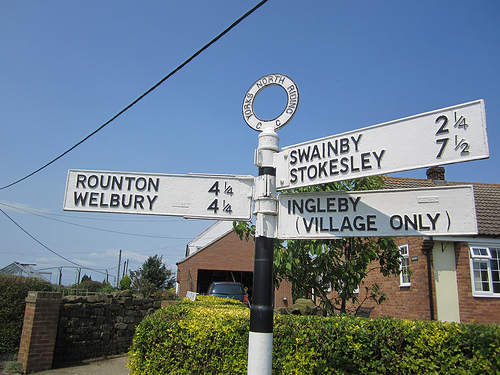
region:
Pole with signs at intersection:
[62, 70, 489, 372]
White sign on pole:
[275, 99, 489, 189]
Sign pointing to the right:
[281, 185, 481, 240]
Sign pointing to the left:
[61, 165, 253, 222]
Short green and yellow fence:
[126, 300, 496, 373]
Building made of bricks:
[176, 175, 498, 321]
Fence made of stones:
[59, 289, 150, 362]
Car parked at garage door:
[207, 279, 245, 306]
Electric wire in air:
[0, 20, 232, 195]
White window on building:
[473, 242, 499, 294]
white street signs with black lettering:
[60, 96, 496, 254]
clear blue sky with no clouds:
[327, 25, 484, 60]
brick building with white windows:
[180, 166, 498, 317]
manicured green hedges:
[139, 312, 476, 371]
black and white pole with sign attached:
[234, 58, 319, 373]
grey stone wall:
[54, 276, 156, 352]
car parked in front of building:
[192, 263, 252, 312]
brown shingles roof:
[475, 175, 495, 240]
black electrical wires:
[2, 0, 297, 205]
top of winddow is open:
[465, 248, 498, 270]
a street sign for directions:
[24, 46, 497, 289]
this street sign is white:
[75, 65, 497, 280]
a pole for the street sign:
[228, 69, 295, 372]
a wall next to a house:
[11, 259, 167, 374]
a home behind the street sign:
[178, 143, 498, 330]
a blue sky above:
[27, 21, 242, 148]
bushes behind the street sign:
[124, 296, 486, 373]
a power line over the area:
[5, 17, 268, 195]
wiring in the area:
[7, 246, 177, 305]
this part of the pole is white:
[222, 313, 288, 373]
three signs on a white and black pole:
[58, 70, 490, 372]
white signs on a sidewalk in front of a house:
[0, 70, 495, 370]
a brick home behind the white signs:
[175, 175, 497, 315]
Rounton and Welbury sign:
[60, 165, 250, 216]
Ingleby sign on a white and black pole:
[275, 182, 476, 237]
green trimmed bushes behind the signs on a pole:
[126, 302, 498, 372]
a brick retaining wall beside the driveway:
[62, 292, 127, 354]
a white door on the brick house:
[431, 244, 460, 321]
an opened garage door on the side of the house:
[194, 270, 251, 303]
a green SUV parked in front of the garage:
[205, 280, 247, 305]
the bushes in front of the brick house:
[126, 290, 498, 373]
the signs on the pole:
[62, 71, 489, 373]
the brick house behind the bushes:
[174, 167, 499, 324]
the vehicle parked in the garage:
[206, 280, 247, 307]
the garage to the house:
[194, 265, 251, 304]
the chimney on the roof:
[426, 164, 446, 179]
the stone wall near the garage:
[48, 289, 175, 366]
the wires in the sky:
[1, 0, 267, 284]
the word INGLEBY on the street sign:
[286, 195, 361, 212]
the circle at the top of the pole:
[243, 73, 298, 132]